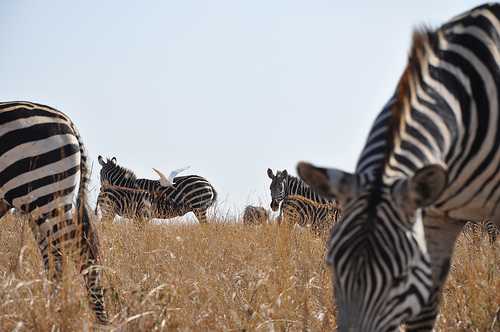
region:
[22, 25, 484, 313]
zebras grazing in brown grass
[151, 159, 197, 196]
white bird in flight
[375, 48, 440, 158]
mane on zebra neck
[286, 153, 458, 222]
two ears on head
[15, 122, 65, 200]
lines on zebra rear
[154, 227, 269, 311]
tall dried brown grass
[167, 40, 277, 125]
light blue daytime sky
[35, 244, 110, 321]
back legs in grass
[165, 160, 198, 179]
extended wing of bird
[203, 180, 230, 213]
tail on back of zebra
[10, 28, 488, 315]
zebras against pale blue sky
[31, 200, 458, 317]
tan and tall grasses around feet and head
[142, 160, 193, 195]
white bird with angled wings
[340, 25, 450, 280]
vertical mane on grazing zebra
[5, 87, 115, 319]
rear legs, buttocks and tail of zebra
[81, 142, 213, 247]
young zebra camouflaged in front of adult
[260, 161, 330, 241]
head turned to left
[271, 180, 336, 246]
rear legs and body of zebra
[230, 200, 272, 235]
oblong form of zebra in distance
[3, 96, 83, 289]
horizontal stripes across backside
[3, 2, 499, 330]
zebras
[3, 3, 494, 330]
zebras in a field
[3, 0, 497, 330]
zebras are standing in a field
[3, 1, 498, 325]
some of the zebras are eating grass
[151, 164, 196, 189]
a white bird flies low with the zebras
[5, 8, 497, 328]
a herd of zebras in a pasture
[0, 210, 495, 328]
the grass is tall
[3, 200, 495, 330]
the grass is brown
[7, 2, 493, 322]
it is a clear sunny day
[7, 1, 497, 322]
the animals are all white and black striped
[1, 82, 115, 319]
a zebra standing in a field.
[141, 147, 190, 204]
a bird landing on a zebra.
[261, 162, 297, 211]
a zebra with big ears.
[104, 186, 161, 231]
the front of a zebra.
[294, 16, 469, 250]
a maine on a zebra.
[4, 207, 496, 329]
dry grass in a field.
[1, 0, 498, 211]
a clear blue sky.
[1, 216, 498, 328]
a field full of dry grass.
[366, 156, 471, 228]
an ear on a zebra.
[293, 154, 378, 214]
the right ear of a zebra.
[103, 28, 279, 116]
this is the sky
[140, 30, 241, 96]
the sky is blue in color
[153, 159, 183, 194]
this is a bird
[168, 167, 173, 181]
the bird is white in color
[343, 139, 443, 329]
this is a zebra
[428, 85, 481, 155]
the zebras has white and black strips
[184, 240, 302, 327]
this is a grass area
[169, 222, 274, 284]
the grass is dry